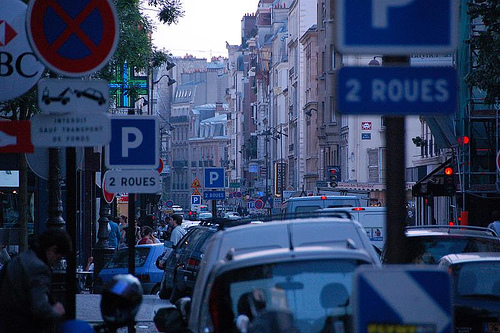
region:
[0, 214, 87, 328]
Man standing under signs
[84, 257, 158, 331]
Silver helmet facing camera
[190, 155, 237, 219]
Blue and white parking sign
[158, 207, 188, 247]
Man wearing a white shirt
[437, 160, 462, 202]
Stop light switched to red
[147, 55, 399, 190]
Clustered building in background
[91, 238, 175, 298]
Rear end of blue car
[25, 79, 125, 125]
White sign illustrating tow truck and car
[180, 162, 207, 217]
Yellow and black consruction signs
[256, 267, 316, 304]
rearview mirror inside of truck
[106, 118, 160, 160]
blue street sign with P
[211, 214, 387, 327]
white van on crowded street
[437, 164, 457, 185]
red lit street light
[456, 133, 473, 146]
red lit street light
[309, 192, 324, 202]
lit rear brake light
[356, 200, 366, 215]
lit rear brake light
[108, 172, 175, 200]
2 roues street sign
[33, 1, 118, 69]
red and blue street sign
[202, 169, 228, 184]
blue street sign with P on it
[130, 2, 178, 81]
tree leaves over street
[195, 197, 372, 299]
these are some cars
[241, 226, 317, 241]
the car is white in color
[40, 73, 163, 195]
these are the signboards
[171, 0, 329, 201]
these are some buildings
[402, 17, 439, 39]
the signboard is blue in color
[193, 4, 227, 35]
this is the sky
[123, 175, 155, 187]
the writings are in bold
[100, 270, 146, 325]
this is a helmet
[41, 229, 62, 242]
the hair is black in color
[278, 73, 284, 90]
the building is white in color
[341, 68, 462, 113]
A blue sign with white wrting.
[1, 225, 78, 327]
A man looking down.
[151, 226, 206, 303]
A car parked on sidewalk.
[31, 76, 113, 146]
A sign with a two truck.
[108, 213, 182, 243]
People walk on the street.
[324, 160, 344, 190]
A red stop light.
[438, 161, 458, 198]
Another red stop light.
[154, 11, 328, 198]
A tall bunch of buildings.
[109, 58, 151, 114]
A light up cross.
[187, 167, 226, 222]
Sign postings all over.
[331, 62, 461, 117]
a blue sign on the post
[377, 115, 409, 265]
a black sign post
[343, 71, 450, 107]
white letters on the sign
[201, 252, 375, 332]
a car windshield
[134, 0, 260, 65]
a gray sky overhead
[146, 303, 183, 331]
a side view mirror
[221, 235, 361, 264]
a rack on the roof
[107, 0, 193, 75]
a green leafy tree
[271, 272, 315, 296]
a rear view mirror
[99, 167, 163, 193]
a white sign